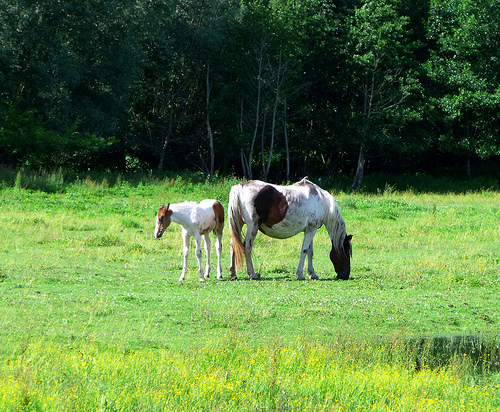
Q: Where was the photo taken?
A: It was taken at the field.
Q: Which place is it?
A: It is a field.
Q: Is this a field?
A: Yes, it is a field.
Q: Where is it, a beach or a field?
A: It is a field.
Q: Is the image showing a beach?
A: No, the picture is showing a field.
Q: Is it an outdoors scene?
A: Yes, it is outdoors.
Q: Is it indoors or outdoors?
A: It is outdoors.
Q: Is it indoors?
A: No, it is outdoors.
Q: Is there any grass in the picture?
A: Yes, there is grass.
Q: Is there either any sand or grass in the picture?
A: Yes, there is grass.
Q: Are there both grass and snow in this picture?
A: No, there is grass but no snow.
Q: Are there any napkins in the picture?
A: No, there are no napkins.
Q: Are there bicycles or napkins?
A: No, there are no napkins or bicycles.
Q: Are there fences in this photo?
A: No, there are no fences.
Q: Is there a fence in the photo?
A: No, there are no fences.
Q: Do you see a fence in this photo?
A: No, there are no fences.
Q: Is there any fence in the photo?
A: No, there are no fences.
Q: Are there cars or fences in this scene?
A: No, there are no fences or cars.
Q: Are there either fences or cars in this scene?
A: No, there are no fences or cars.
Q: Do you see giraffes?
A: No, there are no giraffes.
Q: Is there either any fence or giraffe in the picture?
A: No, there are no giraffes or fences.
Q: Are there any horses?
A: Yes, there is a horse.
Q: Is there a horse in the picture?
A: Yes, there is a horse.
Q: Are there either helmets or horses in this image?
A: Yes, there is a horse.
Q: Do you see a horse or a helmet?
A: Yes, there is a horse.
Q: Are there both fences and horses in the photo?
A: No, there is a horse but no fences.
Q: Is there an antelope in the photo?
A: No, there are no antelopes.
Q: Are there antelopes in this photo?
A: No, there are no antelopes.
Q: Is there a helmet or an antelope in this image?
A: No, there are no antelopes or helmets.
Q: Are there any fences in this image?
A: No, there are no fences.